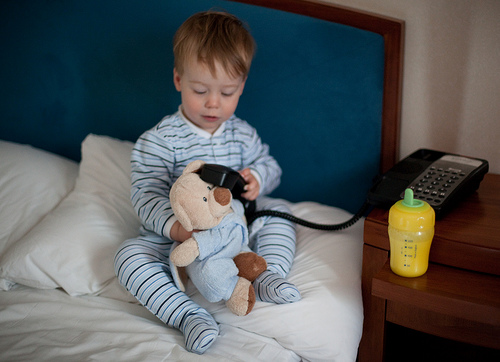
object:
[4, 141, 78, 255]
pillow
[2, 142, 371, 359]
bed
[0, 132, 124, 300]
headrest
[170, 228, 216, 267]
arm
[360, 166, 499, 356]
nightstand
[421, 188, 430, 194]
buttons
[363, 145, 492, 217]
phone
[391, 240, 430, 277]
milk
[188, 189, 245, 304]
outfit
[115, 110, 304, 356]
pajamas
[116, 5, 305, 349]
boy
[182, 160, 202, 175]
bear's ear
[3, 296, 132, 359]
sheet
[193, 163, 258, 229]
phone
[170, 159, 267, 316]
animal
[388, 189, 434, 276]
cup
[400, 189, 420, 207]
top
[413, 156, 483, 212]
keyboard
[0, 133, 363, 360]
pillow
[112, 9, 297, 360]
kid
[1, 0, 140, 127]
background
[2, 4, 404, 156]
headboard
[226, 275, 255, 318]
foot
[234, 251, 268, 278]
foot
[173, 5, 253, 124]
head